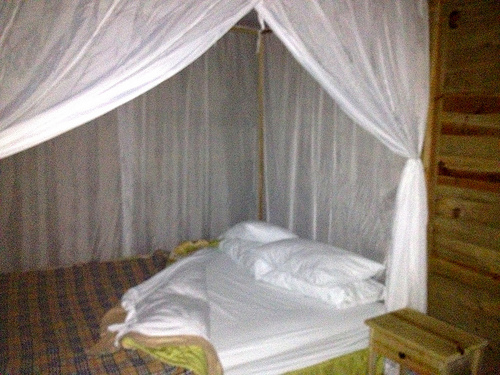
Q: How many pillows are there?
A: Four.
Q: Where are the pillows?
A: On the bed.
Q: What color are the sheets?
A: White.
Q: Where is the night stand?
A: By the bed.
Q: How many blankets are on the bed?
A: Two.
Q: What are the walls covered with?
A: Wood.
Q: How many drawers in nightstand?
A: One.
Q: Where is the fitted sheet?
A: On bed.